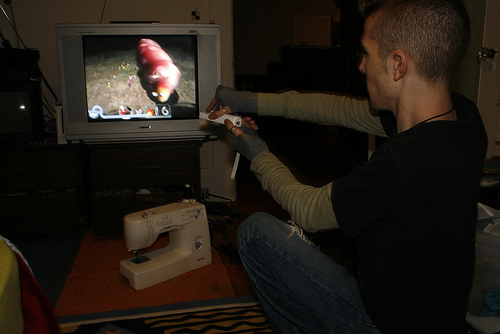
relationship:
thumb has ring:
[224, 118, 244, 142] [228, 124, 236, 132]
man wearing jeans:
[206, 2, 496, 333] [236, 208, 378, 331]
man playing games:
[206, 2, 496, 333] [201, 97, 252, 185]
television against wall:
[58, 23, 224, 144] [2, 0, 233, 205]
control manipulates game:
[199, 108, 242, 132] [83, 33, 201, 119]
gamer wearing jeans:
[206, 2, 496, 333] [236, 208, 378, 331]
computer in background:
[290, 11, 333, 51] [230, 6, 373, 128]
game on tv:
[83, 33, 201, 119] [58, 23, 224, 144]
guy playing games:
[206, 2, 496, 333] [201, 97, 252, 185]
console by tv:
[52, 104, 71, 144] [58, 23, 224, 144]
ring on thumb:
[228, 124, 236, 132] [224, 118, 244, 142]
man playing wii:
[206, 2, 496, 333] [52, 104, 71, 144]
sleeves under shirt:
[217, 82, 395, 239] [330, 86, 473, 334]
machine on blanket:
[122, 197, 211, 290] [57, 220, 234, 321]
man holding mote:
[206, 2, 496, 333] [199, 108, 242, 132]